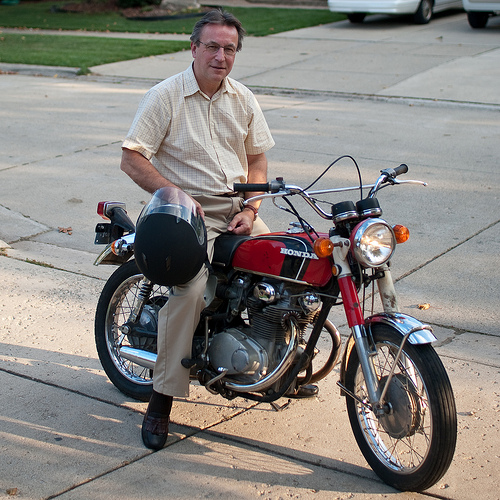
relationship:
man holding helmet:
[118, 9, 277, 452] [132, 184, 211, 291]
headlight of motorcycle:
[352, 218, 396, 268] [83, 150, 460, 496]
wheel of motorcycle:
[343, 313, 459, 493] [83, 150, 460, 496]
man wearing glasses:
[118, 9, 277, 452] [196, 37, 243, 55]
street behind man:
[0, 65, 499, 341] [118, 9, 277, 452]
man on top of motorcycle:
[118, 9, 277, 452] [83, 150, 460, 496]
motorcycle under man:
[83, 150, 460, 496] [118, 9, 277, 452]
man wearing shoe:
[118, 9, 277, 452] [141, 394, 171, 448]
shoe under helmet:
[141, 394, 171, 448] [132, 184, 211, 291]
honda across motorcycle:
[279, 240, 324, 263] [83, 150, 460, 496]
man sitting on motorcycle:
[118, 9, 277, 452] [83, 150, 460, 496]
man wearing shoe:
[112, 9, 276, 448] [141, 394, 171, 448]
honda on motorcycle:
[279, 240, 324, 263] [83, 150, 460, 496]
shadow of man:
[5, 330, 390, 496] [118, 9, 277, 452]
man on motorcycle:
[118, 9, 277, 452] [83, 150, 460, 496]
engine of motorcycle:
[220, 272, 323, 363] [83, 150, 460, 496]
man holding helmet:
[112, 9, 276, 448] [132, 184, 211, 291]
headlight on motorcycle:
[352, 218, 396, 268] [83, 150, 460, 496]